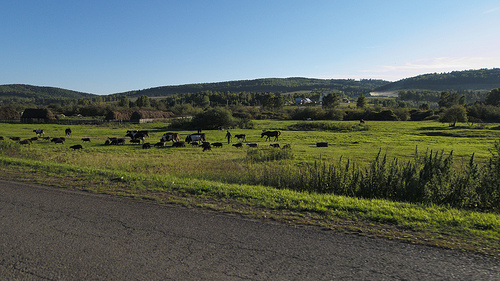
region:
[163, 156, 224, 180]
short green and brown grass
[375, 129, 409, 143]
short green and brown grass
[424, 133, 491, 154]
short green and brown grass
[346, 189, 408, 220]
short green and brown grass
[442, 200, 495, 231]
short green and brown grass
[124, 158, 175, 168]
short green and brown grass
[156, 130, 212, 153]
brown cows in field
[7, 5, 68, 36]
white clouds in blue sky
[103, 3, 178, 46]
white clouds in blue sky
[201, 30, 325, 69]
white clouds in blue sky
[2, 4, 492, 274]
livestock ranch next to highway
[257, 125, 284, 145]
horse walking in pasture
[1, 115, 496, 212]
a large grassy pasture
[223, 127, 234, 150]
person walking in pasture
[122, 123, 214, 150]
livestock grazing in pasture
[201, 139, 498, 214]
weeds at edge of pasture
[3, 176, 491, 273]
road next to pasture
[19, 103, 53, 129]
building next to pasture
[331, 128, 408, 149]
patch of pasture grass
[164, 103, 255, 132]
trees and bushes in pasture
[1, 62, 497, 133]
A hillside full of green trees.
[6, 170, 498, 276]
A paved road.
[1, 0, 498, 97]
A crystal blue sky.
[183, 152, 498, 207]
A patch of green plants.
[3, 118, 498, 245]
A field of green grass.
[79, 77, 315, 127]
trees near a hillside.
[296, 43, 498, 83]
a white haze in a blue sky.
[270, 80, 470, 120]
A patch of green trees.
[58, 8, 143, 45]
A section of blue sky.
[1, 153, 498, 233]
grass on the side of a road.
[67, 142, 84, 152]
This is a sheep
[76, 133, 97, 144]
This is a sheep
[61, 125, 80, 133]
This is a sheep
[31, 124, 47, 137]
This is a sheep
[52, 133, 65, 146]
This is a sheep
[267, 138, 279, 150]
This is a sheep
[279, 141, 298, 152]
This is a sheep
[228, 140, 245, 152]
This is a sheep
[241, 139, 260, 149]
This is a sheep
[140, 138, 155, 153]
This is a sheep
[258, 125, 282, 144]
a horse in the field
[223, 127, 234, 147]
a man in the field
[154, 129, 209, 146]
two cows in the field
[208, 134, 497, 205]
weeds growing on the roadside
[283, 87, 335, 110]
buildings in the background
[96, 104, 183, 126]
these buildings appear to have straw roofs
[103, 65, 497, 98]
hills in the background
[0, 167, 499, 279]
the road is paved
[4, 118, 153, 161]
cattle in the pasture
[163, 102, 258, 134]
bushes at the meadow's edge